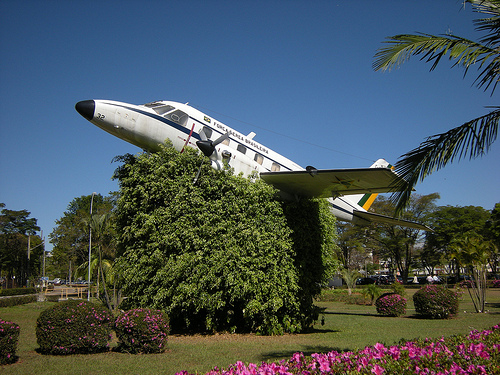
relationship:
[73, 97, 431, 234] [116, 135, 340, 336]
plane in tree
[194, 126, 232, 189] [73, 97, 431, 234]
propeller on plane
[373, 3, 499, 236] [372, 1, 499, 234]
leaves are on palm tree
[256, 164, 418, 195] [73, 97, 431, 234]
wing on plane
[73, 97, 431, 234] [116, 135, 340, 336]
plane on tree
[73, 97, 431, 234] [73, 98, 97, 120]
plane has a nose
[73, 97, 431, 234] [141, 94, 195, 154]
plane has a cockpit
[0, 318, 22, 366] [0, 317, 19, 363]
flowers are on bush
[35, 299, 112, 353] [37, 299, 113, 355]
flowers are on bush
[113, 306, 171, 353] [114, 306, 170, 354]
flowers are on bush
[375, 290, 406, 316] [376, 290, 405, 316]
flowers are on bush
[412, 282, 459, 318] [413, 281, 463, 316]
flowers are on bush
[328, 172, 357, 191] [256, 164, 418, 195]
star on wing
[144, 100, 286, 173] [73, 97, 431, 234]
windows are on plane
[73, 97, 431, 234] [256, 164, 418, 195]
plane has a wing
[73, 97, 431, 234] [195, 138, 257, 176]
plane has an engine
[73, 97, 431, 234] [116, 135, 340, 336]
plane on a tree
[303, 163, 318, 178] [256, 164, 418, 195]
light on wing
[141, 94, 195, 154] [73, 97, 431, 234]
cockpit of plane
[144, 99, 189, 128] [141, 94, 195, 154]
windows are in cockpit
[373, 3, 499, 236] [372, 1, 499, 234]
leaves of a palm tree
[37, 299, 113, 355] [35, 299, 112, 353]
bush with flowers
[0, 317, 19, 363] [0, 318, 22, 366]
bush with flowers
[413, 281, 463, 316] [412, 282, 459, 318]
bush with flowers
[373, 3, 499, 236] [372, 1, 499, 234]
leaves on palm tree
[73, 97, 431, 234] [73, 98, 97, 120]
plane has nose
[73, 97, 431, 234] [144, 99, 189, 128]
plane has windows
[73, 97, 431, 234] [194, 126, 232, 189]
plane has a propeller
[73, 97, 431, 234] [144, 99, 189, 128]
plane has a window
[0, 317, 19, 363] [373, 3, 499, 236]
bush has leaves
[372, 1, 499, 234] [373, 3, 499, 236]
palm tree has leaves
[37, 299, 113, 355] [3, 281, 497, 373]
bush on lawn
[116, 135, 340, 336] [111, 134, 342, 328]
tree has leaves